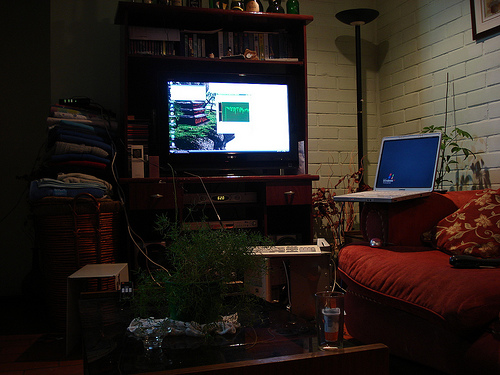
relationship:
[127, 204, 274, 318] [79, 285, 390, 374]
plant on table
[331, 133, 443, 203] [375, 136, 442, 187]
laptop has screen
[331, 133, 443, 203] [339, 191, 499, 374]
laptop on couch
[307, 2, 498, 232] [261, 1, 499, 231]
wall has brick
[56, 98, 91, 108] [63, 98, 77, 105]
box has lights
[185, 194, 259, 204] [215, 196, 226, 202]
box displaying time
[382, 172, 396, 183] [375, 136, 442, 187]
logo on screen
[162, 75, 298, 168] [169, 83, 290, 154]
tv has screen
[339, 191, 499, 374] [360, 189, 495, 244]
couch has arm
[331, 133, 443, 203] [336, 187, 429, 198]
laptop has keyboard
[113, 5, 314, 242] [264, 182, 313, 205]
entertainment center has drawer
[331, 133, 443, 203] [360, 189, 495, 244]
laptop on stand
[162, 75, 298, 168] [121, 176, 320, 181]
tv on shelf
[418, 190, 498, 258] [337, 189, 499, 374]
pillow on sofa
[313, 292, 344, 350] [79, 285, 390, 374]
glass on table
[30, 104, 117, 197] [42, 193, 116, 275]
clothes in basket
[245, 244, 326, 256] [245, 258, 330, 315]
keyboard on box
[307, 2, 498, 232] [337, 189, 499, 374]
wall behind sofa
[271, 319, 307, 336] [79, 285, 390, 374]
dish on table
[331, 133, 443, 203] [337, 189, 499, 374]
laptop on sofa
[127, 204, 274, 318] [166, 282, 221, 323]
plant in pot